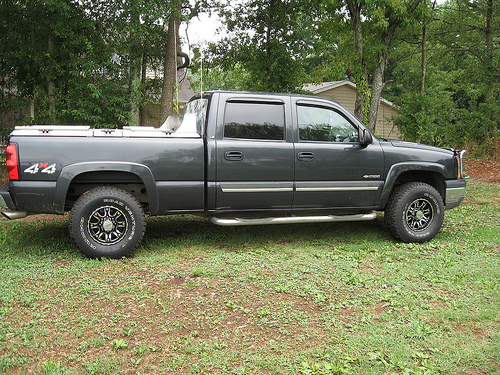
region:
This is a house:
[319, 63, 449, 180]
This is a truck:
[28, 86, 449, 275]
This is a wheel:
[64, 163, 215, 314]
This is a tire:
[56, 171, 175, 281]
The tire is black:
[69, 179, 141, 279]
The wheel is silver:
[101, 214, 118, 234]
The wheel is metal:
[76, 222, 172, 282]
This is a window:
[235, 109, 271, 124]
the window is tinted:
[248, 121, 300, 196]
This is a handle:
[199, 136, 291, 180]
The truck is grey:
[179, 110, 371, 370]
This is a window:
[105, 98, 250, 184]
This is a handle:
[238, 132, 262, 188]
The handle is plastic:
[217, 141, 250, 181]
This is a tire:
[109, 189, 170, 255]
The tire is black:
[90, 171, 196, 273]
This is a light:
[6, 144, 41, 192]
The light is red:
[9, 158, 21, 172]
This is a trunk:
[154, 103, 203, 137]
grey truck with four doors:
[56, 76, 478, 274]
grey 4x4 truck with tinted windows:
[6, 73, 468, 262]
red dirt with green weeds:
[42, 265, 476, 364]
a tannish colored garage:
[302, 64, 443, 146]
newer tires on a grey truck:
[314, 102, 477, 255]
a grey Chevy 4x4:
[5, 74, 480, 269]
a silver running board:
[200, 205, 401, 242]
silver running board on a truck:
[159, 97, 441, 245]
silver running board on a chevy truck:
[147, 72, 493, 234]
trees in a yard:
[256, 23, 479, 147]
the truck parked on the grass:
[2, 89, 469, 258]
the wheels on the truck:
[68, 179, 445, 259]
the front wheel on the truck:
[385, 180, 445, 242]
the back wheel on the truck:
[69, 187, 145, 258]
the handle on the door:
[300, 152, 313, 159]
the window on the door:
[296, 104, 358, 142]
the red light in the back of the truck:
[4, 142, 18, 182]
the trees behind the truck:
[1, 0, 498, 177]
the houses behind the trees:
[2, 21, 418, 182]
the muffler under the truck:
[4, 211, 26, 220]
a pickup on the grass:
[0, 84, 477, 247]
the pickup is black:
[2, 78, 477, 255]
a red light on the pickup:
[0, 143, 22, 183]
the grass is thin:
[6, 227, 486, 373]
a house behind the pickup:
[278, 69, 426, 144]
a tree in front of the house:
[348, 0, 426, 142]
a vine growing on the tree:
[357, 62, 372, 127]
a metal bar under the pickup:
[207, 209, 378, 228]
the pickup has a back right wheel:
[62, 187, 143, 255]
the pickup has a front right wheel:
[389, 178, 444, 244]